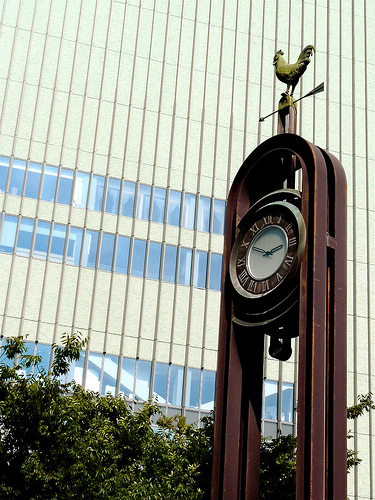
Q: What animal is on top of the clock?
A: Rooster.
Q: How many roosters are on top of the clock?
A: One.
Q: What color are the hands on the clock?
A: Black.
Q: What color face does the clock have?
A: White.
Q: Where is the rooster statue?
A: On top of the clock.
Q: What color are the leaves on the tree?
A: Green.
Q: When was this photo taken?
A: Day time.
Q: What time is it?
A: 2:50.